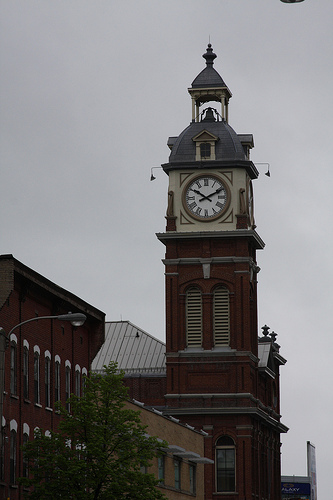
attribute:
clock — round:
[169, 169, 243, 226]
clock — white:
[180, 176, 230, 218]